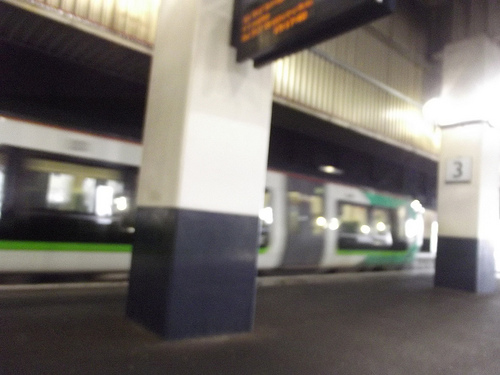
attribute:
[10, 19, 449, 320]
picture — blurry, indoors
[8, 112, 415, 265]
train — white, running, black, moving, green, subway, here, blurry, passing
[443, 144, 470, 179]
number — 3, labeled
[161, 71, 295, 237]
column — black, white, painted, structural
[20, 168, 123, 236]
windows — many, black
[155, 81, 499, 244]
columns — white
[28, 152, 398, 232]
subway — reflecting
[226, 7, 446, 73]
sign — electronic, hanging, black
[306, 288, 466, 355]
floor — grey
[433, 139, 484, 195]
3 — number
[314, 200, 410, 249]
light — reflecting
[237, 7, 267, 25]
letters — orange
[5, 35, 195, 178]
shed — grey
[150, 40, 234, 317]
post — white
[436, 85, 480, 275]
post — numbered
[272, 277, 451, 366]
cement — grey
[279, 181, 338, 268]
doors — shut